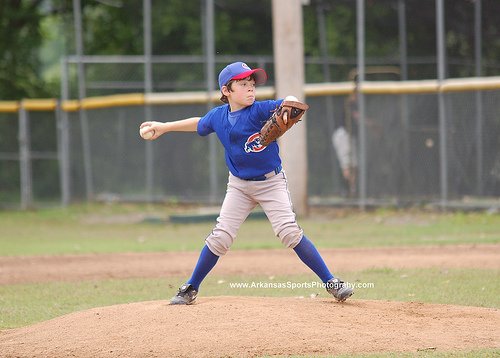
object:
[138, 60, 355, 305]
boy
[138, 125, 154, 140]
ball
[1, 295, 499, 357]
pitcher's mound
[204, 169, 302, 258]
pants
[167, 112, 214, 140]
arm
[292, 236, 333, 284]
sock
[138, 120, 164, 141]
hand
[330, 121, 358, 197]
person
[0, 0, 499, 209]
fence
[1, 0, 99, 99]
tree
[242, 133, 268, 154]
logo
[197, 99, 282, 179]
jersey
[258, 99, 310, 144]
baseball mitt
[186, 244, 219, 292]
sock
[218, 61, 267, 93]
hat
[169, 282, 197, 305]
shoe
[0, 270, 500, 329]
grass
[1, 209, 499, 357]
field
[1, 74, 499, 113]
fence guard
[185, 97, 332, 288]
uniform